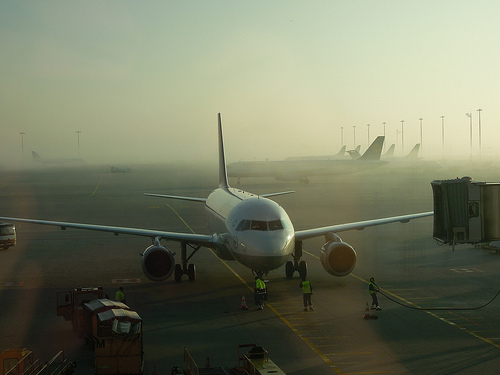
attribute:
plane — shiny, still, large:
[11, 130, 391, 268]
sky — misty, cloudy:
[25, 7, 125, 51]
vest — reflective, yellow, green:
[299, 282, 318, 290]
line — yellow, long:
[267, 321, 336, 365]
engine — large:
[308, 220, 364, 270]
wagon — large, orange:
[57, 280, 172, 359]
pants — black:
[293, 293, 326, 307]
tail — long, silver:
[186, 92, 249, 192]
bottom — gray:
[239, 249, 301, 274]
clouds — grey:
[161, 20, 327, 99]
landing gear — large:
[172, 260, 203, 291]